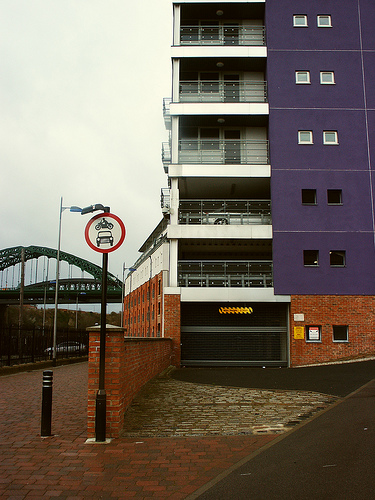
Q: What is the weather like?
A: It is cloudy.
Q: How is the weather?
A: It is cloudy.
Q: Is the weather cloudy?
A: Yes, it is cloudy.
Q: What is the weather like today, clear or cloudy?
A: It is cloudy.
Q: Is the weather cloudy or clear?
A: It is cloudy.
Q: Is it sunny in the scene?
A: No, it is cloudy.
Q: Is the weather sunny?
A: No, it is cloudy.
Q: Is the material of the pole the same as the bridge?
A: Yes, both the pole and the bridge are made of metal.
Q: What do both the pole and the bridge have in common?
A: The material, both the pole and the bridge are metallic.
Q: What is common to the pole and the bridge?
A: The material, both the pole and the bridge are metallic.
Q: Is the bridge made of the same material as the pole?
A: Yes, both the bridge and the pole are made of metal.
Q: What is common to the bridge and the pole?
A: The material, both the bridge and the pole are metallic.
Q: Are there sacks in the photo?
A: No, there are no sacks.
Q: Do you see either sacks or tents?
A: No, there are no sacks or tents.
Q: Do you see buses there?
A: No, there are no buses.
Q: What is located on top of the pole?
A: The sign is on top of the pole.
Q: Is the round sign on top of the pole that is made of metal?
A: Yes, the sign is on top of the pole.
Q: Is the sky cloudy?
A: Yes, the sky is cloudy.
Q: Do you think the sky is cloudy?
A: Yes, the sky is cloudy.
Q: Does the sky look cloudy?
A: Yes, the sky is cloudy.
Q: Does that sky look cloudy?
A: Yes, the sky is cloudy.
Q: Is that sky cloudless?
A: No, the sky is cloudy.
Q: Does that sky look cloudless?
A: No, the sky is cloudy.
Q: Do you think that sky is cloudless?
A: No, the sky is cloudy.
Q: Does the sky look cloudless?
A: No, the sky is cloudy.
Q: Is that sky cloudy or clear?
A: The sky is cloudy.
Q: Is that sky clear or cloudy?
A: The sky is cloudy.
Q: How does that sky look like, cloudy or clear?
A: The sky is cloudy.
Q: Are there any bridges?
A: Yes, there is a bridge.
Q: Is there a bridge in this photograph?
A: Yes, there is a bridge.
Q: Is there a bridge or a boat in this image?
A: Yes, there is a bridge.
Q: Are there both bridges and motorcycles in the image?
A: Yes, there are both a bridge and a motorcycle.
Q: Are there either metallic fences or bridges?
A: Yes, there is a metal bridge.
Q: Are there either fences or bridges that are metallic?
A: Yes, the bridge is metallic.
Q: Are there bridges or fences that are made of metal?
A: Yes, the bridge is made of metal.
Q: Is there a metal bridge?
A: Yes, there is a bridge that is made of metal.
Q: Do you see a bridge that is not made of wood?
A: Yes, there is a bridge that is made of metal.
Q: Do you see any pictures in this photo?
A: No, there are no pictures.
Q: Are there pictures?
A: No, there are no pictures.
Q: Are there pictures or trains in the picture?
A: No, there are no pictures or trains.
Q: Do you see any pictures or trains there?
A: No, there are no pictures or trains.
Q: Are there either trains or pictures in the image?
A: No, there are no pictures or trains.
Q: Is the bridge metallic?
A: Yes, the bridge is metallic.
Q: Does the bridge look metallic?
A: Yes, the bridge is metallic.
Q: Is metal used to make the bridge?
A: Yes, the bridge is made of metal.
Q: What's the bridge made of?
A: The bridge is made of metal.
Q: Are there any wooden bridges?
A: No, there is a bridge but it is metallic.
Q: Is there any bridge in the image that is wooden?
A: No, there is a bridge but it is metallic.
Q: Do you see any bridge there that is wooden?
A: No, there is a bridge but it is metallic.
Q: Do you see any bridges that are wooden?
A: No, there is a bridge but it is metallic.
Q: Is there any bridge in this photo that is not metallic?
A: No, there is a bridge but it is metallic.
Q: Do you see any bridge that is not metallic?
A: No, there is a bridge but it is metallic.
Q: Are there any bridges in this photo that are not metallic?
A: No, there is a bridge but it is metallic.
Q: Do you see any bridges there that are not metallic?
A: No, there is a bridge but it is metallic.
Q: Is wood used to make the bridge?
A: No, the bridge is made of metal.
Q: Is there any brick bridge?
A: No, there is a bridge but it is made of metal.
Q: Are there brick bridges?
A: No, there is a bridge but it is made of metal.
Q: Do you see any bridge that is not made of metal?
A: No, there is a bridge but it is made of metal.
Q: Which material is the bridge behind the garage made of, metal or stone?
A: The bridge is made of metal.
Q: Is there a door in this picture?
A: Yes, there is a door.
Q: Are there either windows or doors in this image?
A: Yes, there is a door.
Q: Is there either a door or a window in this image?
A: Yes, there is a door.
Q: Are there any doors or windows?
A: Yes, there is a door.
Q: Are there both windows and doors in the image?
A: Yes, there are both a door and windows.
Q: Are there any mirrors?
A: No, there are no mirrors.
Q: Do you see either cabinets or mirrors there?
A: No, there are no mirrors or cabinets.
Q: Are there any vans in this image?
A: No, there are no vans.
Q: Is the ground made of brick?
A: Yes, the ground is made of brick.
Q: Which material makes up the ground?
A: The ground is made of brick.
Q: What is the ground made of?
A: The ground is made of brick.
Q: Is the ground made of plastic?
A: No, the ground is made of brick.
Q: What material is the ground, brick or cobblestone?
A: The ground is made of brick.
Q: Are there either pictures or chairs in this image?
A: No, there are no pictures or chairs.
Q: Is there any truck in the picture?
A: No, there are no trucks.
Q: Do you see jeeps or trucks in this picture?
A: No, there are no trucks or jeeps.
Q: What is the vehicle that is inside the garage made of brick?
A: The vehicle is a car.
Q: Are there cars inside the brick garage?
A: Yes, there is a car inside the garage.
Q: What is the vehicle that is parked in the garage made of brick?
A: The vehicle is a car.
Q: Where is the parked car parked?
A: The car is parked in the garage.